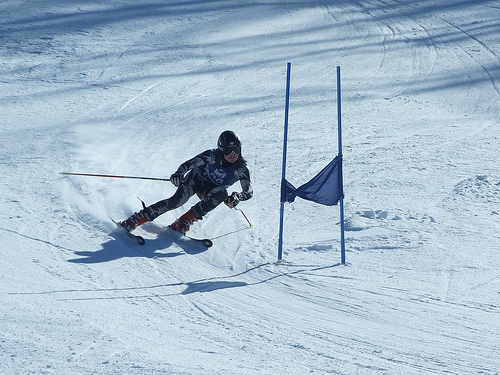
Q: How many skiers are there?
A: One.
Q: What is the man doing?
A: Skiing.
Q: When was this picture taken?
A: Yesterday.